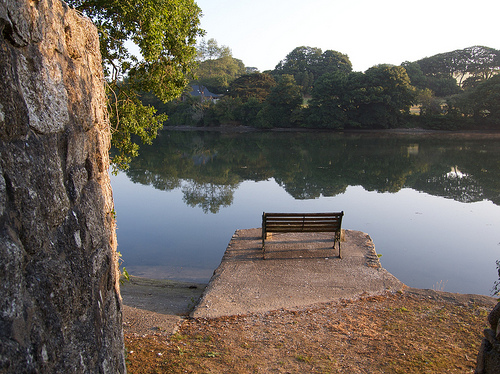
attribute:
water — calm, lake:
[109, 131, 499, 297]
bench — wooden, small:
[261, 212, 343, 259]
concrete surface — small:
[189, 229, 405, 319]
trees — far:
[136, 46, 499, 130]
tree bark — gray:
[0, 0, 127, 374]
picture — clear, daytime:
[0, 1, 498, 374]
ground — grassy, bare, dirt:
[125, 286, 500, 373]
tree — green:
[67, 0, 206, 170]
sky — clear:
[123, 1, 499, 70]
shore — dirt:
[162, 124, 499, 135]